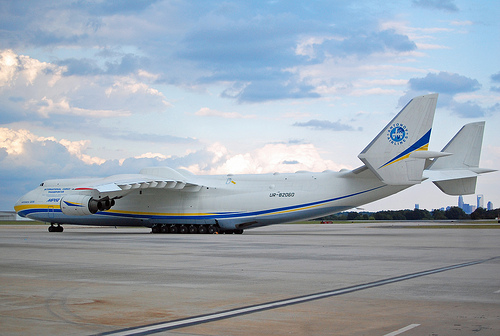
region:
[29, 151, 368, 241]
airplane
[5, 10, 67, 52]
white clouds in blue sky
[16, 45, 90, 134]
white clouds in blue sky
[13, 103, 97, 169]
white clouds in blue sky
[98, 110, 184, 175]
white clouds in blue sky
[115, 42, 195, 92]
white clouds in blue sky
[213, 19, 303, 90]
white clouds in blue sky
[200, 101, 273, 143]
white clouds in blue sky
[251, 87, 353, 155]
white clouds in blue sky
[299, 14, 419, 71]
white clouds in blue sky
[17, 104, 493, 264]
the plane is white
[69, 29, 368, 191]
big, white and gray clouds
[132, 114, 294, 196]
big, white and gray clouds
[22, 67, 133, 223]
big, white and gray clouds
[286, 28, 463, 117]
big, white and gray clouds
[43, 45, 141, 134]
big, white and gray clouds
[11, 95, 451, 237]
White airplane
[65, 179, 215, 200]
Left wing of the airplane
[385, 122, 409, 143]
Logo on the tail of the airplane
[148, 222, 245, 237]
Set of wheels on the back of the airplane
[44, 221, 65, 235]
Wheels in front of the airplane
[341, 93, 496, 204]
Tail of the airplane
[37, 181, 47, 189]
Front window of the airplane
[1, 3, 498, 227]
Clear blue sky with clouds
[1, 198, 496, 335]
Road way used by the airplane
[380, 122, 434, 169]
Stripes of the tail of the airplane.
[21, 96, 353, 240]
white and blue airplane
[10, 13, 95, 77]
blue sky with no clouds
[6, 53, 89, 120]
blue sky with no clouds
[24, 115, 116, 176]
blue sky with no clouds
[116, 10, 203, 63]
blue sky with no clouds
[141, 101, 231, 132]
blue sky with no clouds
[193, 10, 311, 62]
blue sky with no clouds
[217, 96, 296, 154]
blue sky with no clouds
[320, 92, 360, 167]
blue sky with no clouds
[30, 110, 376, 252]
white airplane on run way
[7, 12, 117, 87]
blu sky with no clouds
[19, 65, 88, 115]
blu sky with no clouds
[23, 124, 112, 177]
blu sky with no clouds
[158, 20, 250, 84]
blu sky with no clouds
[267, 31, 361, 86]
blu sky with no clouds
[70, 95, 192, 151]
blu sky with no clouds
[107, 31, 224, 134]
blu sky with no clouds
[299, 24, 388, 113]
blu sky with no clouds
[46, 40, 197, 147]
blu sky with no clouds